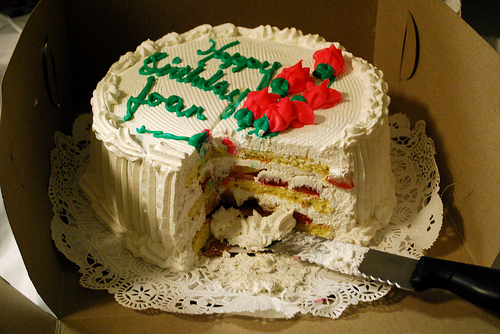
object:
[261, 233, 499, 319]
knife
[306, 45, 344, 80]
roses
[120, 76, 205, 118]
words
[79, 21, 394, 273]
cake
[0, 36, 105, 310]
fold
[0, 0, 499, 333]
cardboard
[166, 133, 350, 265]
filing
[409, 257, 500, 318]
handle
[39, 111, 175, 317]
paper